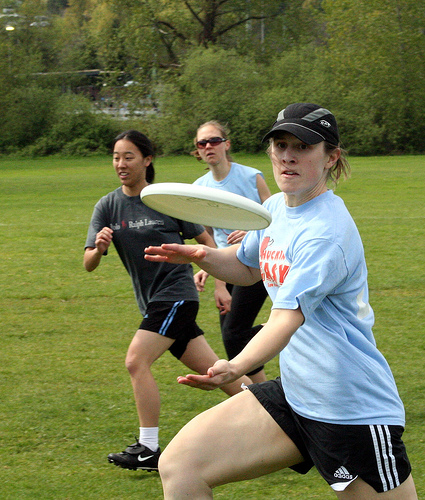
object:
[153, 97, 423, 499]
people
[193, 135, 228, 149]
sunglasses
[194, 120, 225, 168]
face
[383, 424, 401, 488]
stripes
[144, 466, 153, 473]
cleats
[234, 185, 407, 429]
shirt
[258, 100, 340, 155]
hat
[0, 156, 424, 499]
grass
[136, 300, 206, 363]
shorts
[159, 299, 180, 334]
stripe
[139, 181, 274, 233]
frisbee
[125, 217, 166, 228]
word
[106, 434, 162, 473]
shoe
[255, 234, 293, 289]
logo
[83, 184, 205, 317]
shirt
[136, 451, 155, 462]
logo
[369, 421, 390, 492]
stripe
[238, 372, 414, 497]
pants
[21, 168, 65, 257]
air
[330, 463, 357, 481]
adidas symbol